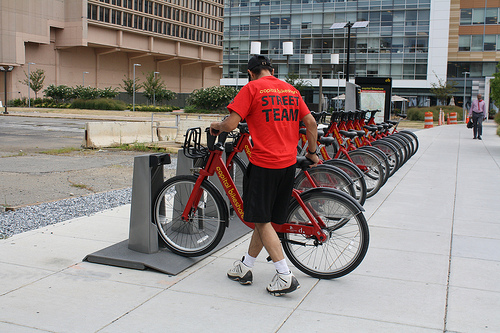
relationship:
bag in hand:
[464, 119, 474, 134] [461, 86, 487, 141]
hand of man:
[461, 86, 487, 141] [462, 106, 474, 120]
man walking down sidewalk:
[466, 92, 485, 141] [16, 119, 498, 330]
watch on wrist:
[308, 149, 316, 156] [304, 144, 323, 169]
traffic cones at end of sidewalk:
[414, 98, 471, 128] [422, 128, 490, 306]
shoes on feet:
[272, 272, 297, 294] [231, 233, 338, 321]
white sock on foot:
[242, 252, 257, 271] [266, 274, 301, 296]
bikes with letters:
[127, 105, 427, 284] [209, 156, 246, 226]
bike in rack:
[161, 97, 457, 320] [101, 117, 249, 324]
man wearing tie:
[462, 88, 489, 139] [478, 99, 483, 115]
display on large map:
[335, 57, 446, 152] [356, 80, 392, 130]